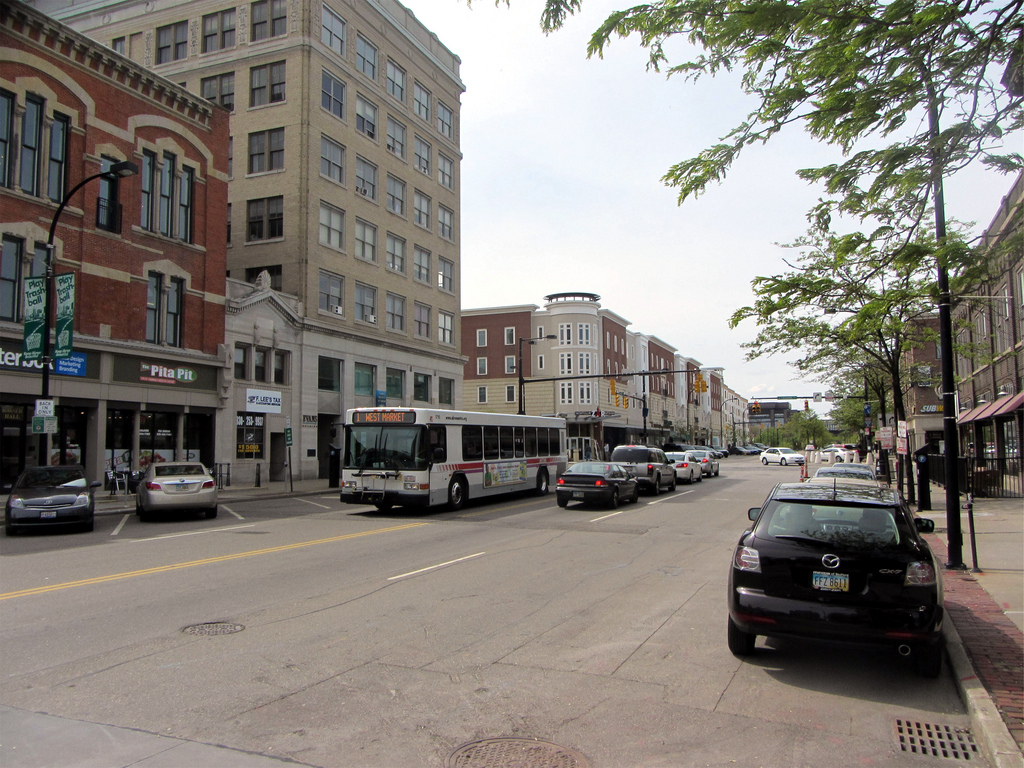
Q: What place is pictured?
A: It is a street.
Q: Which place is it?
A: It is a street.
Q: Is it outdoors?
A: Yes, it is outdoors.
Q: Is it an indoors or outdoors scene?
A: It is outdoors.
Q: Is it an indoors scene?
A: No, it is outdoors.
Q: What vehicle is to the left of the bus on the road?
A: The vehicle is a car.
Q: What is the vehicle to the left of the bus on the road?
A: The vehicle is a car.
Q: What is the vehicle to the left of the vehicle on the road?
A: The vehicle is a car.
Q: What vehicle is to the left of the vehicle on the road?
A: The vehicle is a car.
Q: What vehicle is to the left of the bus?
A: The vehicle is a car.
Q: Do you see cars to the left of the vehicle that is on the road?
A: Yes, there is a car to the left of the bus.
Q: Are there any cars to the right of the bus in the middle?
A: No, the car is to the left of the bus.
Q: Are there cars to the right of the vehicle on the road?
A: No, the car is to the left of the bus.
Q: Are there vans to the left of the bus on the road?
A: No, there is a car to the left of the bus.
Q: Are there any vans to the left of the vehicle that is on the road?
A: No, there is a car to the left of the bus.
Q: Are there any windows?
A: Yes, there is a window.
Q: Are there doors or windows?
A: Yes, there is a window.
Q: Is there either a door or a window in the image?
A: Yes, there is a window.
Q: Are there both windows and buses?
A: Yes, there are both a window and a bus.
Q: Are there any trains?
A: No, there are no trains.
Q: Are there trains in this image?
A: No, there are no trains.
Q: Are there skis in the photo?
A: No, there are no skis.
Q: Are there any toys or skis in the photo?
A: No, there are no skis or toys.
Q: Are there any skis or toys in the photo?
A: No, there are no skis or toys.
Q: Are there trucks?
A: No, there are no trucks.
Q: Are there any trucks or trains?
A: No, there are no trucks or trains.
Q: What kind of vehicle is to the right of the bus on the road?
A: The vehicles are cars.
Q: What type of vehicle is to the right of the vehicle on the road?
A: The vehicles are cars.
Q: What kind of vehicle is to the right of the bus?
A: The vehicles are cars.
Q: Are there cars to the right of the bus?
A: Yes, there are cars to the right of the bus.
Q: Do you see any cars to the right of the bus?
A: Yes, there are cars to the right of the bus.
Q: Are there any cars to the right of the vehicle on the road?
A: Yes, there are cars to the right of the bus.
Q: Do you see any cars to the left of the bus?
A: No, the cars are to the right of the bus.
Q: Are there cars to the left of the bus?
A: No, the cars are to the right of the bus.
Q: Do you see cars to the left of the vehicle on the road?
A: No, the cars are to the right of the bus.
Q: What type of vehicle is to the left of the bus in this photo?
A: The vehicle is a car.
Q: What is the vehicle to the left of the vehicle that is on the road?
A: The vehicle is a car.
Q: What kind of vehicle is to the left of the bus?
A: The vehicle is a car.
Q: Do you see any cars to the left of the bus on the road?
A: Yes, there is a car to the left of the bus.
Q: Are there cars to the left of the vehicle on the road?
A: Yes, there is a car to the left of the bus.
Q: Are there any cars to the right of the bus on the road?
A: No, the car is to the left of the bus.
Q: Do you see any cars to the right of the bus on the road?
A: No, the car is to the left of the bus.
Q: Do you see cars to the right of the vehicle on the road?
A: No, the car is to the left of the bus.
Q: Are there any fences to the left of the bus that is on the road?
A: No, there is a car to the left of the bus.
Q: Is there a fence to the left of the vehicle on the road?
A: No, there is a car to the left of the bus.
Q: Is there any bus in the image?
A: Yes, there is a bus.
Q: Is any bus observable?
A: Yes, there is a bus.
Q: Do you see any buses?
A: Yes, there is a bus.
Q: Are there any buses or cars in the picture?
A: Yes, there is a bus.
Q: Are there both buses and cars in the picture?
A: Yes, there are both a bus and a car.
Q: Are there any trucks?
A: No, there are no trucks.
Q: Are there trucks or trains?
A: No, there are no trucks or trains.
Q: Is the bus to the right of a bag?
A: No, the bus is to the right of the car.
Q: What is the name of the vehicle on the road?
A: The vehicle is a bus.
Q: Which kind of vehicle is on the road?
A: The vehicle is a bus.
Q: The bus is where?
A: The bus is on the road.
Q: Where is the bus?
A: The bus is on the road.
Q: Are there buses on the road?
A: Yes, there is a bus on the road.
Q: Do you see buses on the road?
A: Yes, there is a bus on the road.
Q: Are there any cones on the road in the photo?
A: No, there is a bus on the road.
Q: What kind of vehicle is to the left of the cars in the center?
A: The vehicle is a bus.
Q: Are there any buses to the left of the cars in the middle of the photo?
A: Yes, there is a bus to the left of the cars.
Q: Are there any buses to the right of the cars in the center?
A: No, the bus is to the left of the cars.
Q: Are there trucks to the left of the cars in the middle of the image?
A: No, there is a bus to the left of the cars.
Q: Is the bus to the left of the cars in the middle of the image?
A: Yes, the bus is to the left of the cars.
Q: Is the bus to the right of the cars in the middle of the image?
A: No, the bus is to the left of the cars.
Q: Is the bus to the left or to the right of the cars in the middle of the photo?
A: The bus is to the left of the cars.